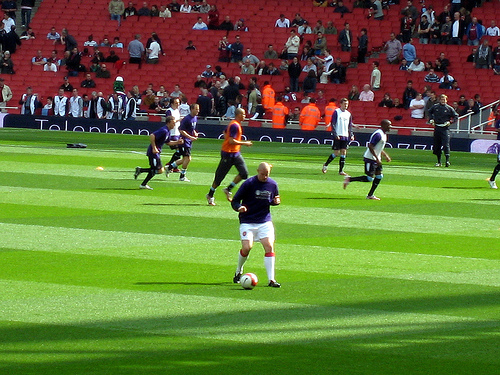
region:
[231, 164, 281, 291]
man about to hit a soccer ball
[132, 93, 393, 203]
men running on a soccer field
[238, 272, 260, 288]
a red and white soccer ball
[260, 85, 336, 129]
men wearing orange security coats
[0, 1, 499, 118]
people sitting in the bleacher watching a soccer game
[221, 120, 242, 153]
man wearing an orange security vest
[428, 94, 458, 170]
man standing on the side of a soccer field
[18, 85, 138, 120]
people standing up watching a soccer game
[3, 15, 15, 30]
man wearing a white shirt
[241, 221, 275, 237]
man wearing white shorts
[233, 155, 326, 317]
the man is playing with a ball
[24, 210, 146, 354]
the grass is green in colour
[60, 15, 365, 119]
the spectators are seated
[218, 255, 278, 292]
the ball is white in colour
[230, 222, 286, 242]
the short is white in colour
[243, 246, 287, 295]
the socks are white in colour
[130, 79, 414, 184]
the men are wearing a uniform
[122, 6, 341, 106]
the seats are red in colour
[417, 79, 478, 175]
the man is holding his waist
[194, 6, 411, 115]
people are seated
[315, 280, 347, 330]
part of a filed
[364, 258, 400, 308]
part of a ground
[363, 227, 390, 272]
part of a field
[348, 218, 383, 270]
part of a carpet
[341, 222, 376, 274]
part of a gound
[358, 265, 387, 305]
part of a ground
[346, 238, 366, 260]
part of a line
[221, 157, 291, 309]
Man getting ready to kick soccer ball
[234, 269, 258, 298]
Red and white soccer ball with black emblem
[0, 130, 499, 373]
Green surfaced soccer field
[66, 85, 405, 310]
Adult males playing soccer on a green field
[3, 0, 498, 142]
Spectators sitting in seats watching soccer game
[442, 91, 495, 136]
White metal stair railing in stands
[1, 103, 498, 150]
Navy blue divider with words printed on it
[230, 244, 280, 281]
White knee high soccer socks with red rims around tops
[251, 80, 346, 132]
Four people in stands with neon orange coats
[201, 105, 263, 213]
Soccer player wearing an orange vest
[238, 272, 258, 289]
the soccer ball on the grass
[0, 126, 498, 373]
the lush green grass on the field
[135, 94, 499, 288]
the people on the field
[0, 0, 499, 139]
the audience in the stands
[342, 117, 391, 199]
the man running on the grass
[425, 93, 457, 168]
the man standing on the grass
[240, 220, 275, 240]
the man's white shorts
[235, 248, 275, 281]
the man's high socks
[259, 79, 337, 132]
the people dressed in bright orange clothing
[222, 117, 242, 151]
the orange tanktop on the man